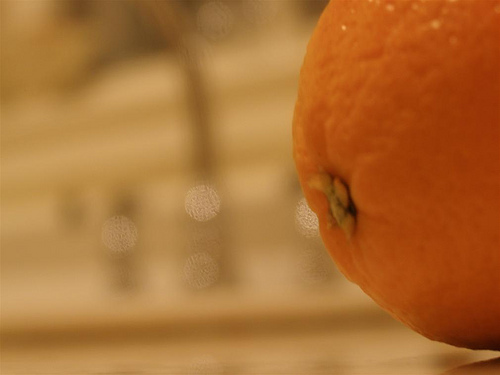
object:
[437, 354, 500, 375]
shadow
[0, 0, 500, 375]
bad image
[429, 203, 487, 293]
peel part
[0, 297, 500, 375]
counter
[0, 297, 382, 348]
sink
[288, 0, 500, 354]
fruit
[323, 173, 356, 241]
stalk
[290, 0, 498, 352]
peel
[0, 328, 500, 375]
table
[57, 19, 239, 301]
faucet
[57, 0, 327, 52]
window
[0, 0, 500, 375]
kitchen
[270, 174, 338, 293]
lever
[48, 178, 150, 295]
lever